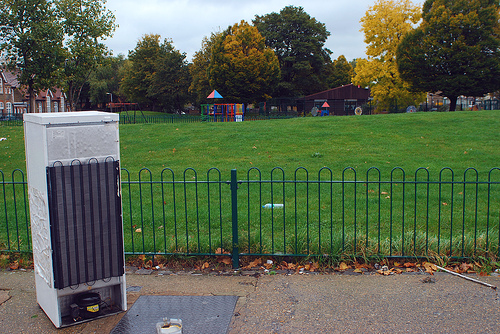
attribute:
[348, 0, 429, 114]
leaves — golden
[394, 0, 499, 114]
leaves — golden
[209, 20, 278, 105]
leaves — golden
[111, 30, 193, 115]
leaves — golden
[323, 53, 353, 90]
leaves — golden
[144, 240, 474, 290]
leaves — dry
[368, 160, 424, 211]
ground — recreational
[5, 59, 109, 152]
house — brown, white, brick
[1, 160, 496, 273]
fencing — black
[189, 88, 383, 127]
playground — childrens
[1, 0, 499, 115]
trees — leafy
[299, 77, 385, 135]
house — brown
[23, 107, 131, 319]
fridge — trash, white, abandoned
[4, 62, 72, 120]
building — large, red, brick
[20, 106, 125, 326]
refrigerator — discarded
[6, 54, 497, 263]
park — local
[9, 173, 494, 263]
fence — green, metal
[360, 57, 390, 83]
leaves — yellow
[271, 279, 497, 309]
sidewalk — wet, cement